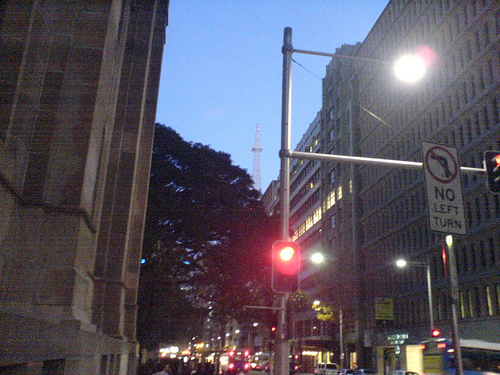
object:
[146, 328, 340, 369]
lights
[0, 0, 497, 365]
outside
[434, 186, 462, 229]
words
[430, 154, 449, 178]
arrow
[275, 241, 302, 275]
red light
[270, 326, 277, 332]
red light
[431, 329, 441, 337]
red light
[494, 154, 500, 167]
red light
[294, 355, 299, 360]
red light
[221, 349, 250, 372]
car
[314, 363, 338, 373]
car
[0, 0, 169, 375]
building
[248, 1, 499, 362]
building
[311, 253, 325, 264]
light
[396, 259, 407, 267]
light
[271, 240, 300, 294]
light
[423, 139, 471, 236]
sign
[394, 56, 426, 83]
light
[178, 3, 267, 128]
sky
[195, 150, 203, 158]
leaves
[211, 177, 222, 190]
leaves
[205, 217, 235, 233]
leaves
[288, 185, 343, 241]
lights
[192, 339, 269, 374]
traffic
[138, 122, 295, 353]
tree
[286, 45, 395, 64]
horizontal pole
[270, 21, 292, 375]
pole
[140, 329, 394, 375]
street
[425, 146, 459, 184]
circle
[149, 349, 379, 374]
city street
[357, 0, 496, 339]
face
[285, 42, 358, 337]
face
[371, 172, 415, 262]
windows